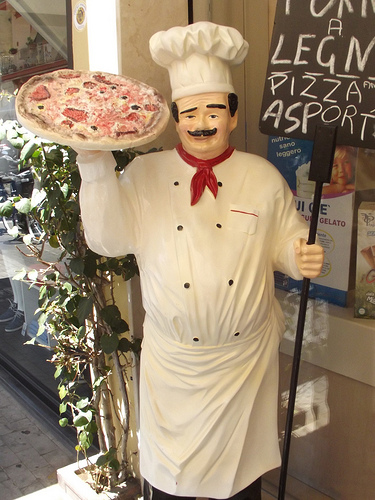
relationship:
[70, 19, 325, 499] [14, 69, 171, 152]
body holding pizza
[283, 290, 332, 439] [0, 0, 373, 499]
reflection on wall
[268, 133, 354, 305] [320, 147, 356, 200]
picture of baby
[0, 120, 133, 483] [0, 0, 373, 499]
plant against wall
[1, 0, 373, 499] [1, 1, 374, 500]
outside during daytime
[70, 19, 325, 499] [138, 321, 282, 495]
body wearing apron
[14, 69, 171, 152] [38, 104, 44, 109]
pizza has olives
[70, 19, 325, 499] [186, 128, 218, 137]
body has mustache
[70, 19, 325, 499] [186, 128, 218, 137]
body wears mustache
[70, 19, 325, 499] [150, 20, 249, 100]
body wears chef hat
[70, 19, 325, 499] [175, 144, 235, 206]
body wears bandana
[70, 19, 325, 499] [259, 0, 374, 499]
body hold sign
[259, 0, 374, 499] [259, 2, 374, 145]
sign with italian language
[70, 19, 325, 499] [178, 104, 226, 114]
body has eyebrow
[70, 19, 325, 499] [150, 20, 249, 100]
body has chef hat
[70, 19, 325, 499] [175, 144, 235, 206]
body has red kerchief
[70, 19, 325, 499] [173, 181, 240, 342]
body has buttons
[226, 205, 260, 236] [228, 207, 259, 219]
pocket has pocket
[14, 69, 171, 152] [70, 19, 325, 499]
pizza part of body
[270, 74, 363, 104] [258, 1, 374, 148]
pizza on chalkboard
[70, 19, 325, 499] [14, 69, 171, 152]
body bearing pizza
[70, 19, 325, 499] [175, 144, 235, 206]
body has scarf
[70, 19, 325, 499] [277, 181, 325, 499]
body hold stick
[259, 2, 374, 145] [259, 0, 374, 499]
writing on sign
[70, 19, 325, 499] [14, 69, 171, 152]
body hold pizza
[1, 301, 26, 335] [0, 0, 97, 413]
shoes in window